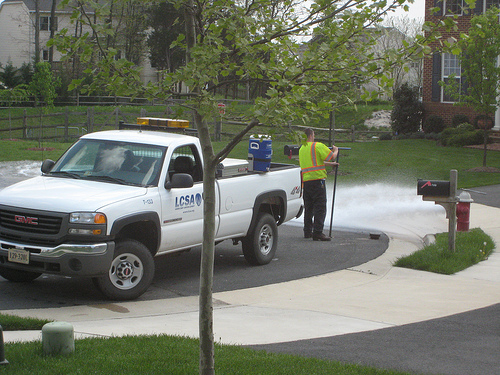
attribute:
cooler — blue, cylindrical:
[246, 135, 274, 176]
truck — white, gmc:
[1, 116, 306, 304]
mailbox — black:
[416, 178, 454, 199]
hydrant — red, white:
[453, 189, 473, 235]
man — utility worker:
[297, 127, 339, 242]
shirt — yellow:
[299, 141, 334, 182]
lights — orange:
[137, 116, 191, 131]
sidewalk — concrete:
[5, 179, 499, 347]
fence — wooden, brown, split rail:
[0, 111, 396, 154]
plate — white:
[7, 247, 32, 266]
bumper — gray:
[0, 243, 117, 279]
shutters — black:
[431, 0, 489, 107]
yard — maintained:
[0, 135, 499, 191]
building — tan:
[0, 0, 209, 102]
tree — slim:
[57, 5, 401, 373]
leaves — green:
[9, 2, 487, 134]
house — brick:
[422, 0, 500, 153]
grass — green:
[392, 225, 500, 280]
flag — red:
[420, 180, 434, 189]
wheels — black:
[93, 212, 279, 304]